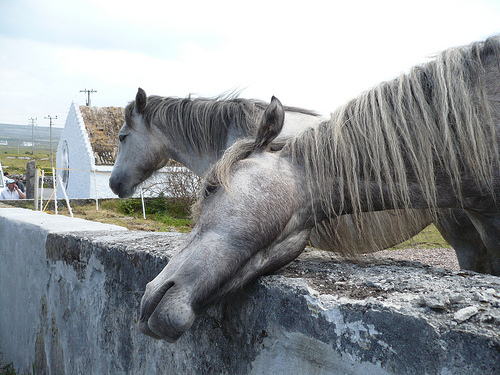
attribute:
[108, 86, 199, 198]
horse — grey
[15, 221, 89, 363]
wall — chipped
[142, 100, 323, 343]
head — shaggy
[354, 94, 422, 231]
mane — shaggy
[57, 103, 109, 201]
building — white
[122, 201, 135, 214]
bush — green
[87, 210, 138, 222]
road — dirt